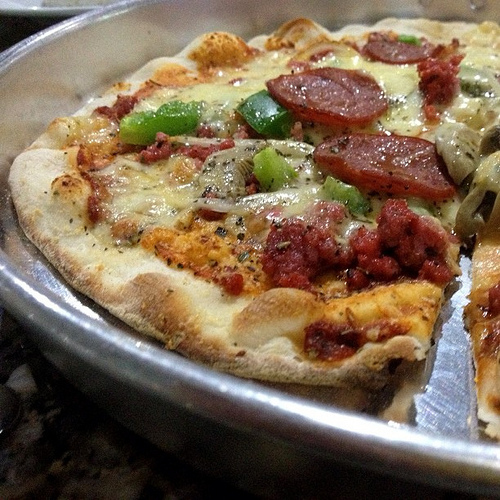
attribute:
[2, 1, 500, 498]
pan — silver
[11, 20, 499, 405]
pizza — sliced, cut, crusty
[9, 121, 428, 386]
crust — burnt, brown, bubbly, think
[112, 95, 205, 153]
peppers — green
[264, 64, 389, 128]
pepperoni — big, red, cooked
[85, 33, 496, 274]
cheese — yellow, shiny, melted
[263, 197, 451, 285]
sauce — red, chunky